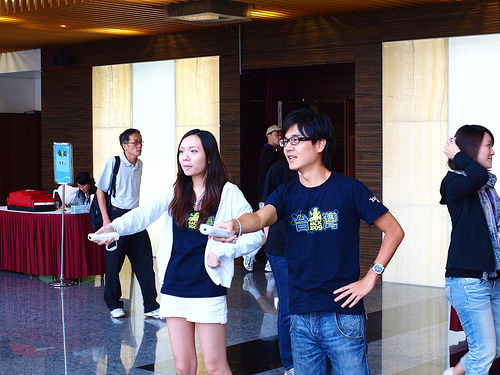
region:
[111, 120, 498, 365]
there are some people in the room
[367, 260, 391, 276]
a watch on the man's wrist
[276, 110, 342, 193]
the man is wearing spectacles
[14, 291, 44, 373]
the floor is made of tiles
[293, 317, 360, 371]
this is a pair of jeans trousers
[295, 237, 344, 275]
the t-shirt is black in color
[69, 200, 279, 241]
they are holding remotes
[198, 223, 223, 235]
the remote is white in color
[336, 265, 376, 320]
the man is holding his waist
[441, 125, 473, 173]
the woman is holding her hair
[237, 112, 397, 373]
this is a man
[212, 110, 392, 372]
the man is holding a remote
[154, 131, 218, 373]
a man is beside the man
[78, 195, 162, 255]
her hand is in front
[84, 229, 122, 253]
the remote is white in color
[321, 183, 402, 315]
the mans hand is on his waiste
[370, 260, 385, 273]
he is wearing a wrist watch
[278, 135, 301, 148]
he has spectacles on his eyes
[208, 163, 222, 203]
the lady has long hair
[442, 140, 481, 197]
the womans right hand is touching her hair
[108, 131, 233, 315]
woman holding game controller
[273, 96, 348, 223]
man wearing glasses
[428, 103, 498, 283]
woman wearing a long scarf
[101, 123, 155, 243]
older man in glasses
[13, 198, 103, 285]
table with red curtain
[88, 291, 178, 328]
man with white shoes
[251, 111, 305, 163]
man wearing beige cap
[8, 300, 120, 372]
gray shiny floor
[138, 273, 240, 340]
woman in short skirt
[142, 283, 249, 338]
the short is white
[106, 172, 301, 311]
the jacket is white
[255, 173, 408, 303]
the shirt is blue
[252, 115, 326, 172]
the man is wearing eyeglasses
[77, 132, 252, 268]
the woman is holding console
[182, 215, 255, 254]
the wii is white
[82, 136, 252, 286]
the woman is wearing a jacket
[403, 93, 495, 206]
a woman is scratching her head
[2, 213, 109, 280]
the tablecloth is red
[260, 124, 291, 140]
the cap is brown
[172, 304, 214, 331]
part of a white short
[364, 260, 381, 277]
a wrist watch on the left hand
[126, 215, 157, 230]
part of a white jumper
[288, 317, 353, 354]
part of a jeans trouser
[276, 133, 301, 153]
spectacles of a man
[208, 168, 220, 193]
hair of the lady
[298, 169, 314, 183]
neck of the man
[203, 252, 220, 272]
left hand of the lady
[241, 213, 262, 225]
right arm of the man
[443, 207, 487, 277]
part of a dark sweater